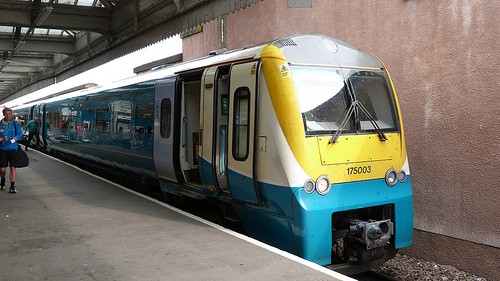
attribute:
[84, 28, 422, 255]
train — yellow, blue, yellow blue, whit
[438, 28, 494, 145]
wall — red, white, brown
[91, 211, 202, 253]
pavement — gray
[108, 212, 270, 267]
platform — concrete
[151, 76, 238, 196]
door — ajar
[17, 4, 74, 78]
overhang — metal